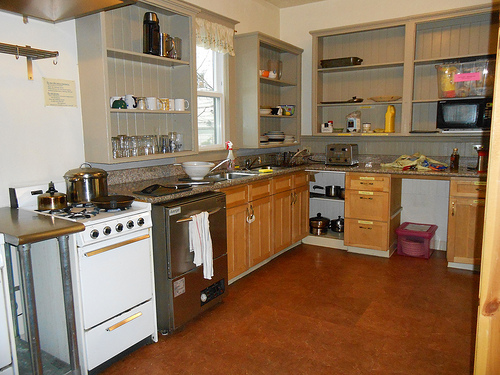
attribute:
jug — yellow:
[384, 103, 401, 130]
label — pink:
[451, 75, 479, 85]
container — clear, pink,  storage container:
[430, 57, 498, 102]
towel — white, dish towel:
[187, 208, 224, 286]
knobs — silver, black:
[89, 217, 163, 247]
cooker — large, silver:
[63, 150, 112, 206]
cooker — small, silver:
[319, 182, 341, 196]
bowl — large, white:
[175, 156, 216, 184]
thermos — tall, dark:
[140, 50, 164, 53]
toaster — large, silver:
[315, 136, 360, 168]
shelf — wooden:
[107, 122, 168, 164]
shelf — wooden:
[81, 105, 177, 175]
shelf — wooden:
[100, 101, 164, 149]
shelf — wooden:
[90, 104, 209, 171]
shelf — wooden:
[104, 121, 188, 163]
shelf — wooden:
[102, 118, 198, 167]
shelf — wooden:
[108, 112, 197, 168]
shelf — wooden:
[111, 113, 194, 163]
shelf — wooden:
[106, 114, 191, 166]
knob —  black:
[80, 228, 106, 241]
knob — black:
[93, 226, 101, 233]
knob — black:
[86, 230, 96, 241]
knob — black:
[106, 228, 116, 232]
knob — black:
[118, 216, 125, 231]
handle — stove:
[79, 230, 147, 260]